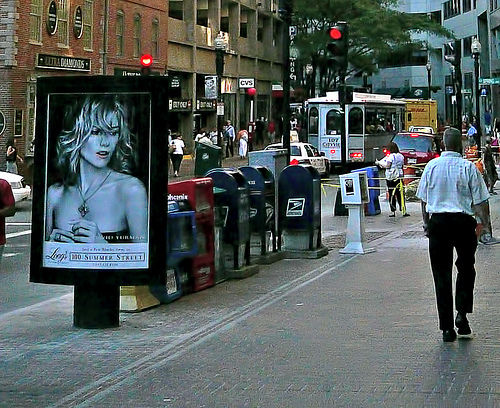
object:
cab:
[263, 140, 332, 179]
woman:
[373, 140, 411, 218]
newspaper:
[375, 153, 391, 168]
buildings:
[168, 0, 292, 157]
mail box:
[276, 162, 329, 260]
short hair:
[441, 125, 462, 152]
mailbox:
[202, 165, 260, 280]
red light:
[328, 27, 342, 40]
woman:
[43, 90, 149, 247]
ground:
[0, 167, 500, 407]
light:
[326, 23, 346, 74]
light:
[470, 32, 482, 55]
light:
[140, 53, 153, 66]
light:
[212, 32, 224, 49]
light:
[426, 62, 432, 71]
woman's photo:
[43, 91, 152, 247]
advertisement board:
[27, 73, 174, 330]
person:
[4, 137, 24, 175]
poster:
[40, 91, 151, 271]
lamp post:
[470, 33, 483, 159]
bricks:
[273, 382, 292, 391]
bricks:
[358, 385, 378, 393]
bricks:
[285, 339, 290, 343]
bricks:
[146, 343, 159, 350]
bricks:
[383, 350, 396, 357]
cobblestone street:
[0, 178, 500, 408]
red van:
[385, 130, 441, 167]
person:
[267, 119, 277, 143]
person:
[168, 134, 186, 178]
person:
[221, 124, 230, 159]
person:
[237, 125, 249, 159]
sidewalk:
[13, 140, 287, 203]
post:
[247, 147, 290, 179]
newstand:
[337, 170, 377, 255]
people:
[222, 119, 236, 158]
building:
[0, 0, 171, 190]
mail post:
[202, 166, 261, 279]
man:
[413, 126, 494, 343]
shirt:
[413, 149, 491, 216]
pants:
[427, 210, 480, 331]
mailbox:
[235, 163, 285, 264]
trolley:
[303, 90, 407, 167]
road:
[3, 150, 500, 408]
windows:
[113, 6, 124, 59]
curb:
[0, 291, 68, 318]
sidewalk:
[0, 207, 500, 408]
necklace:
[74, 168, 114, 217]